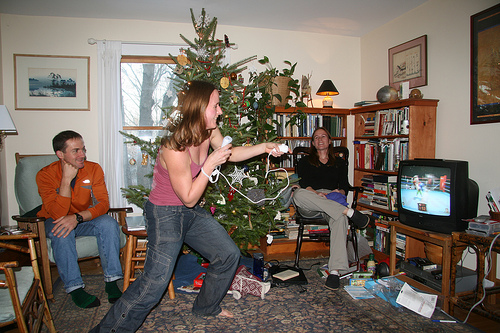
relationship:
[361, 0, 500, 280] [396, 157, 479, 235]
wall behind tv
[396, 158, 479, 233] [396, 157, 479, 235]
case on tv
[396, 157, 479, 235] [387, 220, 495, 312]
tv on desk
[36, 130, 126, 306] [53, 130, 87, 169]
man has head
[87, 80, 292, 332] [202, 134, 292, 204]
lady holding controller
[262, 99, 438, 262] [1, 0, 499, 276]
bookcase against wall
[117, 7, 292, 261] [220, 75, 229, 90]
tree has ornament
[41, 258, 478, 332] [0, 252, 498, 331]
rug on ground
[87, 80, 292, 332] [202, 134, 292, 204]
lady hold controller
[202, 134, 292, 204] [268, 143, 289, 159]
controller in hand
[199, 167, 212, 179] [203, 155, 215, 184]
strap on wrist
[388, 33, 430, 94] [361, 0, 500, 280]
picture on wall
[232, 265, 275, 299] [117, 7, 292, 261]
present under tree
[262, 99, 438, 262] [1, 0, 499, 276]
bookcase on wall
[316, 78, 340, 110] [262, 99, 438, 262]
lamp on bookcase